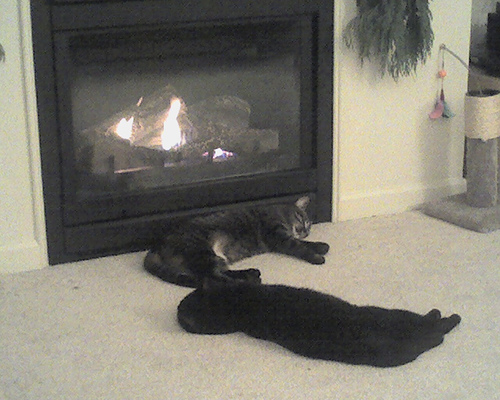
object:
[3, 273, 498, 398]
floor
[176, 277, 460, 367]
fur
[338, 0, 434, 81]
hanging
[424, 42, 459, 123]
hanging down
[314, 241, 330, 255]
paw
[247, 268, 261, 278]
paw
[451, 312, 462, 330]
paw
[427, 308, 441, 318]
paw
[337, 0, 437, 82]
fern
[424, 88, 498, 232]
post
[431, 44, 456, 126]
toy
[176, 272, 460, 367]
cat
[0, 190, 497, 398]
carpet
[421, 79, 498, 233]
stand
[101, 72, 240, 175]
fire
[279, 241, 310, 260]
leg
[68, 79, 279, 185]
fire place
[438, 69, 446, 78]
ball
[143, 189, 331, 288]
cat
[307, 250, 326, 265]
left paw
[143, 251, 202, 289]
tail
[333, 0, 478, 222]
wall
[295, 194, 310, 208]
ear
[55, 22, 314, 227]
fireplace